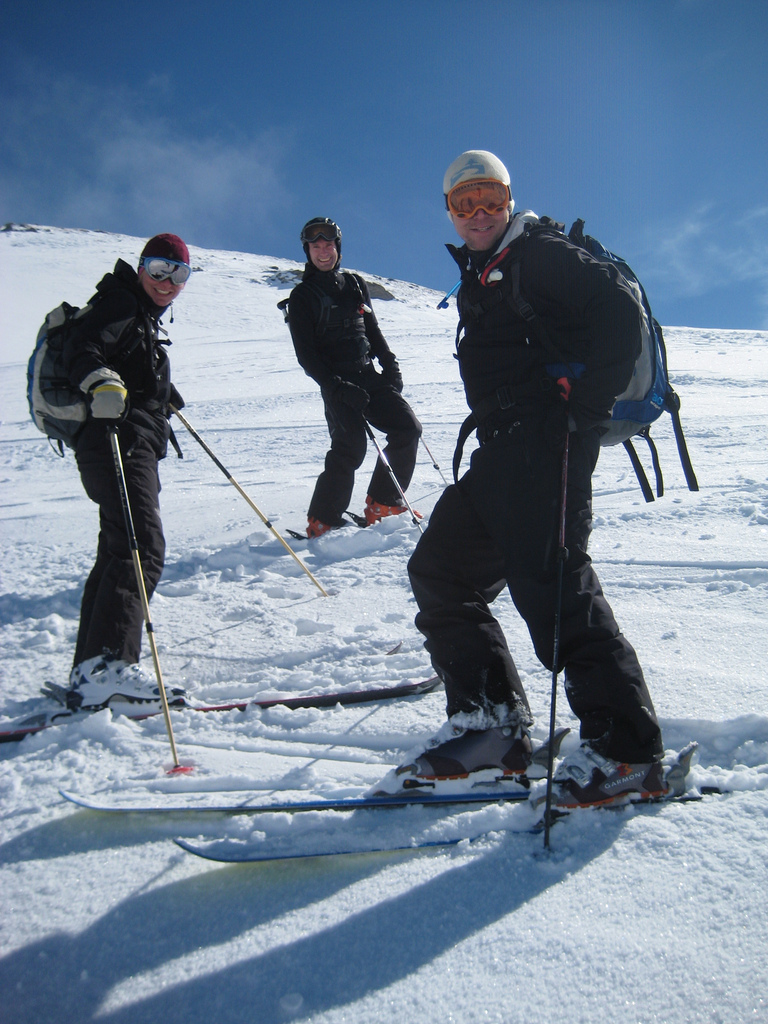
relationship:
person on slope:
[32, 125, 706, 799] [4, 216, 768, 1024]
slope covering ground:
[4, 216, 768, 1024] [4, 389, 767, 1021]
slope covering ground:
[4, 216, 768, 1024] [2, 219, 744, 1016]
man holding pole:
[407, 157, 666, 816] [527, 396, 584, 877]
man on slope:
[407, 157, 666, 816] [4, 207, 744, 1018]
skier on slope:
[288, 216, 423, 539] [4, 207, 744, 1018]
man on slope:
[69, 233, 192, 722] [4, 207, 744, 1018]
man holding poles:
[69, 233, 192, 722] [108, 421, 195, 777]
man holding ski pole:
[69, 233, 192, 722] [171, 407, 317, 595]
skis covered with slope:
[63, 763, 765, 867] [4, 216, 768, 1024]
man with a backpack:
[69, 233, 192, 722] [28, 298, 90, 444]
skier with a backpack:
[285, 219, 421, 513] [276, 296, 302, 357]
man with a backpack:
[407, 157, 666, 816] [581, 215, 695, 497]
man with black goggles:
[69, 233, 192, 722] [136, 252, 190, 288]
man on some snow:
[69, 233, 192, 722] [165, 579, 349, 689]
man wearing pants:
[47, 221, 232, 722] [84, 523, 191, 662]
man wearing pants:
[69, 233, 192, 722] [77, 442, 164, 712]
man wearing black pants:
[69, 233, 192, 722] [60, 469, 228, 848]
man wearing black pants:
[69, 233, 192, 722] [78, 425, 152, 665]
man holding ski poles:
[69, 233, 192, 722] [68, 513, 312, 799]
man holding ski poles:
[69, 233, 192, 722] [116, 469, 234, 572]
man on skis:
[455, 257, 629, 712] [142, 758, 683, 882]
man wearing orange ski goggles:
[407, 157, 666, 816] [448, 182, 526, 229]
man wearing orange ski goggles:
[407, 157, 666, 816] [440, 190, 514, 230]